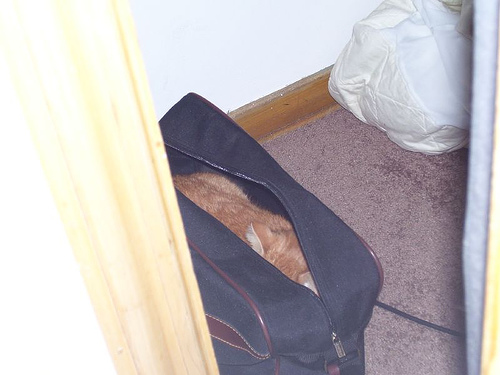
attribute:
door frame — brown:
[21, 0, 199, 372]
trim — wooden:
[6, 1, 179, 372]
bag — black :
[144, 69, 384, 372]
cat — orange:
[165, 159, 317, 297]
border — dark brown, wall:
[225, 66, 344, 150]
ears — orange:
[239, 224, 263, 262]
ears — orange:
[258, 231, 290, 270]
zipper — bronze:
[328, 329, 348, 359]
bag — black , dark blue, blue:
[154, 87, 389, 374]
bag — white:
[320, 3, 473, 163]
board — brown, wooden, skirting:
[223, 66, 339, 153]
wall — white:
[125, 0, 399, 165]